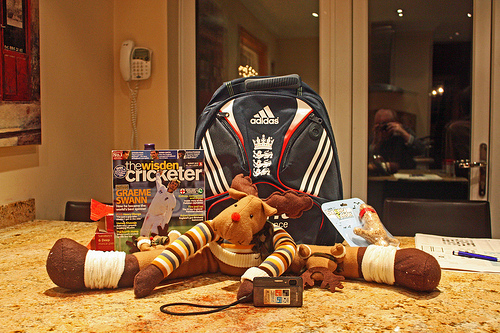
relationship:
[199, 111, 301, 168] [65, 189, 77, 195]
backpack on floor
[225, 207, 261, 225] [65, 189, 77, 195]
animal on floor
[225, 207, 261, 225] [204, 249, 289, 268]
animal wearing shirt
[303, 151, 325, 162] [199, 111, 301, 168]
lines on backpack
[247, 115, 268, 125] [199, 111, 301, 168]
logo on backpack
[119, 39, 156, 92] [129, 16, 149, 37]
phone on wall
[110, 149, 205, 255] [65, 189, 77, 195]
book on floor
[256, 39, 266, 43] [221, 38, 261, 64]
reflection in window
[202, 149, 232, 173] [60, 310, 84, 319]
camera on counter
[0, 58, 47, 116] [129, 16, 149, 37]
art on wall